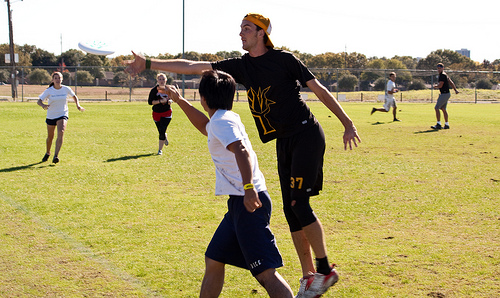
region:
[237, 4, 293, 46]
orange and white hat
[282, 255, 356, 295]
red and white shoes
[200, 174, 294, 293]
blue shorts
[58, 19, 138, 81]
white frisbee in the air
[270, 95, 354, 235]
black shorts on a man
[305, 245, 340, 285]
black ankle brace on a mans ankle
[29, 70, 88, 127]
girl wearing a white tee shirt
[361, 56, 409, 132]
a man running wearing white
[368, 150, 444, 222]
grass on the field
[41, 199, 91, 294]
white striped line on the field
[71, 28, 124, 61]
white frisbee in flight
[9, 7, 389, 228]
man throwing white frisbee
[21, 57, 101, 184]
girl in white playing frisbee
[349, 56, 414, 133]
guy with a footbal running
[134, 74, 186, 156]
girl in black playing frisbee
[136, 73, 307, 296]
young boy playing frisbee with group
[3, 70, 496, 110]
fence seperating the fields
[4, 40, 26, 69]
transformer on utility pole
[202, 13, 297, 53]
man wearing backwards facing hat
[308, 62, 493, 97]
sprinklers going in farther field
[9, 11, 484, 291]
a group of kids playing with a frisbee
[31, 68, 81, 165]
girl in a white shirt running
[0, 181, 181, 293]
short green grass in a field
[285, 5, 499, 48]
bright sunny sky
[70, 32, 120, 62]
white frisbee in the air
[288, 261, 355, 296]
red and white sports cleats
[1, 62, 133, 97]
chain linked fence bordering field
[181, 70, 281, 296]
a boy reaching for a frisbee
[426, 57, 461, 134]
a boy wearing a dark shirt and shorts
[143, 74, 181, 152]
running girl wearing a red shirt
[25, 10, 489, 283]
a group of young people playing with a frisbee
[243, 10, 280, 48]
bright yellow baseball cap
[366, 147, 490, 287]
green grass in a sports field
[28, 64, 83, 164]
running girl wearing a white shirt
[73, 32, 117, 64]
a white frisbee in motion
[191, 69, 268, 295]
boy wearing white shirt and blue pants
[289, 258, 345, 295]
red and white sneakers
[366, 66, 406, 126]
a boy wearing white and running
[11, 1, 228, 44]
bright sunny skies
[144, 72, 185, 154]
a girl running toward the frisbee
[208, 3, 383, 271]
Man wearing a black shirt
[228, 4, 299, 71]
Man wearing a yellow and white hat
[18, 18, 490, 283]
People on a grass field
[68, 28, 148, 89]
The frisbee is white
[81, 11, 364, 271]
The man is reaching for the frisbee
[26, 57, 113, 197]
The girl is running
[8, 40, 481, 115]
The fence is grey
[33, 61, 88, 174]
Girl wearing a white shirt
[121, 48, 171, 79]
Man is wearing a black bracelet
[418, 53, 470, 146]
Man wearing grey shorts